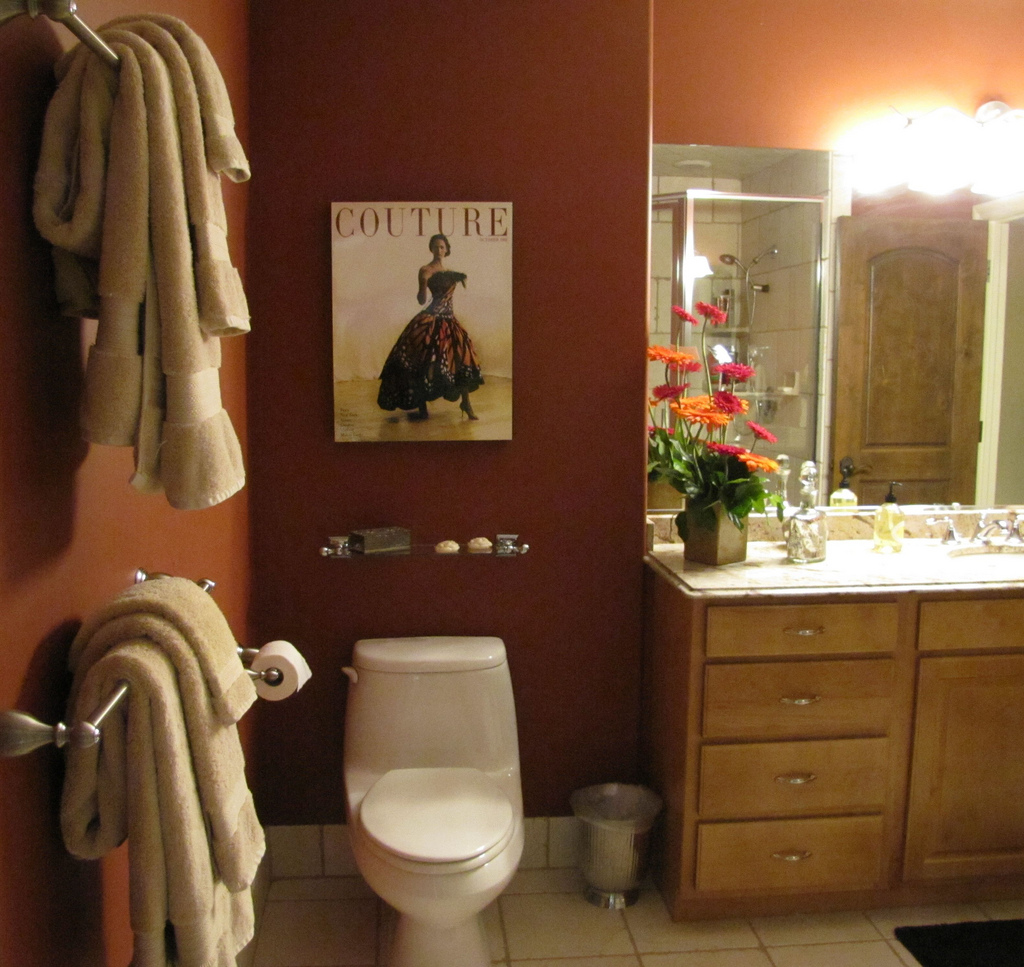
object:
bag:
[569, 783, 664, 835]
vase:
[684, 495, 749, 563]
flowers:
[747, 420, 779, 454]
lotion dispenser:
[873, 482, 905, 553]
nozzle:
[885, 481, 902, 503]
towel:
[35, 7, 251, 516]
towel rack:
[2, 4, 123, 69]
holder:
[236, 649, 279, 685]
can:
[570, 783, 665, 912]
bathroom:
[0, 0, 1024, 967]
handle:
[780, 693, 821, 703]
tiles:
[499, 893, 641, 963]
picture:
[329, 201, 513, 443]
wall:
[243, 0, 656, 832]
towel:
[58, 576, 266, 967]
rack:
[0, 577, 224, 767]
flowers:
[671, 301, 698, 325]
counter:
[644, 536, 1024, 604]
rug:
[892, 916, 1024, 967]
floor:
[235, 818, 1024, 967]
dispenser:
[250, 640, 311, 701]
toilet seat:
[358, 768, 516, 878]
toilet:
[343, 635, 527, 967]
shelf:
[318, 544, 529, 557]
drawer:
[706, 604, 900, 658]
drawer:
[701, 659, 896, 739]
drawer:
[693, 732, 887, 821]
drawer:
[695, 815, 886, 891]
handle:
[783, 626, 826, 635]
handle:
[777, 774, 816, 784]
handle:
[772, 852, 811, 861]